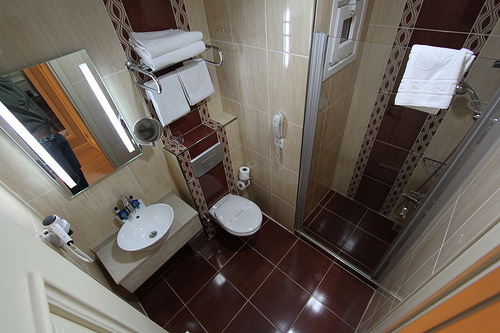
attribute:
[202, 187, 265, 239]
toilet — white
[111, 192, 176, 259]
sink — white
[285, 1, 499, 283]
door — glass, shower door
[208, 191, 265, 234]
toilet — white, porcelain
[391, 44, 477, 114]
towel — white, hanging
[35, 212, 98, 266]
dryer — blow dryer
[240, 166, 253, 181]
toilet paper — roll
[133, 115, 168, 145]
mirror — round, swivel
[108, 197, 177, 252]
sink — white, bathroom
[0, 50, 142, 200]
mirror — glass, wall, mounted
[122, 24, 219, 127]
towels — white, folded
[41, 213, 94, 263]
hair dryer — white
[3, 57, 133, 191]
mirror — rectangular, bathroom mirror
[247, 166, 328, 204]
wall — white, hand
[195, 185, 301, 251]
toliet — white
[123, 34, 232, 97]
towel rack — metal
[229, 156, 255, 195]
rolls — toilet tissue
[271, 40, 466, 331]
door — shower door, glass